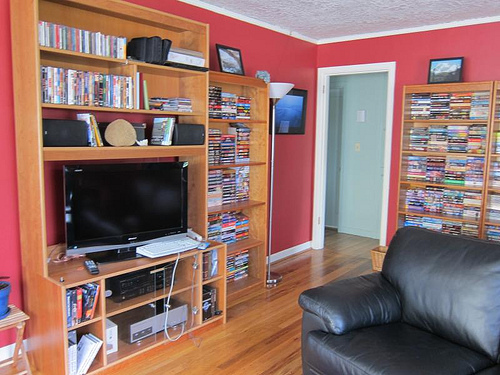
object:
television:
[56, 157, 194, 265]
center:
[7, 0, 231, 374]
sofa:
[294, 203, 499, 374]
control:
[81, 260, 99, 280]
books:
[34, 16, 207, 115]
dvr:
[113, 261, 191, 295]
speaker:
[41, 113, 91, 152]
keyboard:
[131, 234, 204, 265]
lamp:
[260, 72, 298, 301]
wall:
[0, 0, 500, 350]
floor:
[4, 221, 499, 374]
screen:
[61, 160, 195, 257]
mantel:
[0, 0, 286, 373]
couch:
[295, 214, 499, 374]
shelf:
[17, 20, 230, 160]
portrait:
[270, 82, 308, 136]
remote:
[76, 254, 112, 283]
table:
[0, 297, 32, 375]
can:
[369, 242, 392, 273]